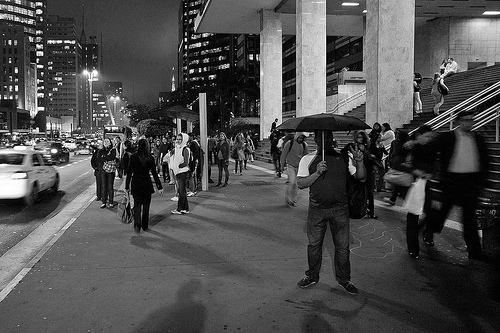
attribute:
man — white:
[298, 131, 359, 290]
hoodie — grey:
[281, 130, 308, 172]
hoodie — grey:
[166, 131, 197, 177]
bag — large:
[436, 80, 450, 95]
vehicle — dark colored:
[23, 130, 76, 175]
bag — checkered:
[91, 146, 121, 185]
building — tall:
[52, 30, 89, 133]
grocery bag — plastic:
[399, 170, 434, 222]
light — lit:
[67, 47, 128, 133]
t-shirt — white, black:
[297, 148, 359, 208]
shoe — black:
[287, 273, 383, 306]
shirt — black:
[286, 144, 363, 214]